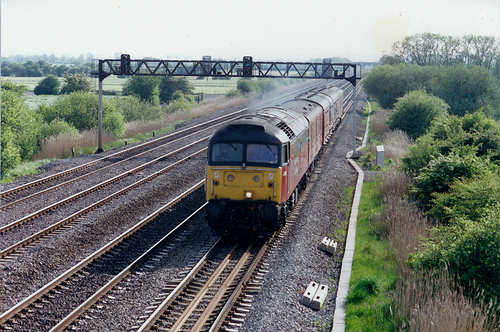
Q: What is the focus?
A: Train coming down tracks.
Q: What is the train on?
A: Railroad tracks.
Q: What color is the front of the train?
A: Yellow.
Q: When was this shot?
A: Daytime.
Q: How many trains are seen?
A: 1.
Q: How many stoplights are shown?
A: 4.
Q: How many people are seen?
A: 0.